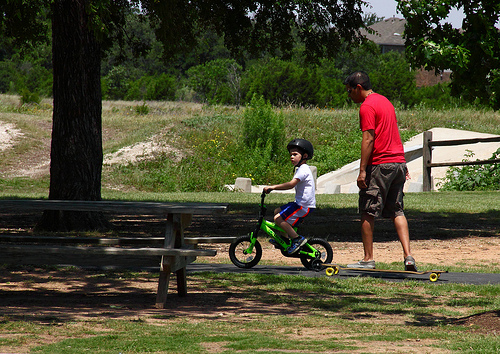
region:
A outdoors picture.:
[15, 7, 491, 342]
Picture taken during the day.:
[22, 35, 447, 345]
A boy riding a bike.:
[226, 125, 331, 278]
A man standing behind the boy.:
[337, 67, 420, 274]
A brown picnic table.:
[15, 195, 226, 300]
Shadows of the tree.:
[66, 191, 347, 237]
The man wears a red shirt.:
[351, 100, 403, 156]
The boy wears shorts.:
[276, 200, 308, 225]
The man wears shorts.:
[360, 170, 408, 211]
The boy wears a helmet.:
[289, 136, 314, 157]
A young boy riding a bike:
[227, 128, 337, 284]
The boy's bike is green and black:
[227, 188, 339, 268]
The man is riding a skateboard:
[338, 70, 450, 300]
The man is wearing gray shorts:
[353, 157, 412, 223]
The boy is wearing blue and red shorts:
[278, 199, 313, 230]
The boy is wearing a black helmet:
[285, 135, 316, 163]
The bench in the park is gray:
[2, 191, 227, 308]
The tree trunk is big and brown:
[29, 3, 118, 237]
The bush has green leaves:
[206, 87, 290, 177]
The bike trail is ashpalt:
[214, 257, 495, 287]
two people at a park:
[119, 40, 447, 350]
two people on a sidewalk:
[204, 45, 487, 337]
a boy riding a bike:
[203, 116, 378, 315]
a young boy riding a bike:
[222, 122, 363, 337]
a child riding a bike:
[211, 115, 346, 303]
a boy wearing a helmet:
[229, 121, 334, 271]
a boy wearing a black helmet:
[215, 102, 350, 273]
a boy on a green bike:
[204, 112, 361, 287]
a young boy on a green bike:
[207, 98, 347, 283]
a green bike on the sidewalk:
[229, 107, 336, 289]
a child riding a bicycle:
[215, 129, 337, 276]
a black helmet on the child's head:
[286, 135, 317, 160]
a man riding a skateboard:
[319, 67, 456, 277]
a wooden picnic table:
[0, 193, 250, 309]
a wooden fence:
[403, 131, 498, 197]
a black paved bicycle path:
[92, 255, 497, 280]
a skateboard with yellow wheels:
[320, 256, 451, 285]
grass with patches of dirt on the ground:
[1, 255, 499, 352]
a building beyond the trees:
[346, 8, 455, 91]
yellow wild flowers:
[187, 126, 233, 167]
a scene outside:
[3, 1, 477, 351]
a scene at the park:
[12, 9, 497, 349]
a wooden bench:
[0, 183, 250, 328]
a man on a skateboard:
[307, 46, 459, 296]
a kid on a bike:
[216, 131, 358, 291]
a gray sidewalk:
[0, 226, 498, 306]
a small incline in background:
[0, 82, 498, 226]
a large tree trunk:
[32, 0, 123, 211]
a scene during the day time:
[9, 8, 497, 340]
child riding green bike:
[231, 118, 335, 276]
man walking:
[355, 82, 430, 293]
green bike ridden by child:
[235, 208, 325, 275]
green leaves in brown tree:
[145, 18, 210, 36]